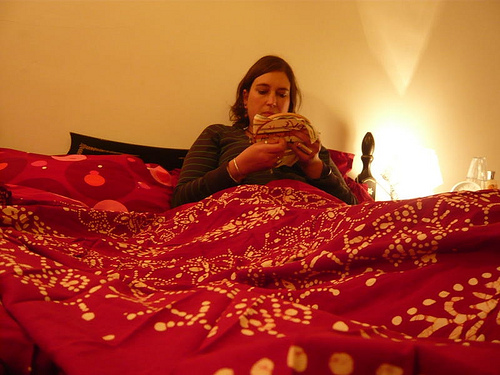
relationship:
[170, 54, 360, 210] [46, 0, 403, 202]
lady on bed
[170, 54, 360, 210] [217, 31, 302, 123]
lady has head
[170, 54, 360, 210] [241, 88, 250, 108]
lady has ear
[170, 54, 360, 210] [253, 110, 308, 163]
lady reads book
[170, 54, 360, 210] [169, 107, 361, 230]
lady wears sweater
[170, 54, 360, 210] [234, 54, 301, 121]
lady has brown hair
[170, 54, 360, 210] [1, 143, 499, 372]
lady in bed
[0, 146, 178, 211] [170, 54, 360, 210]
pillow next lady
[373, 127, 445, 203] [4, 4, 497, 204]
light on wall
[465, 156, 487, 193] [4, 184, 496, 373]
glassware near blanket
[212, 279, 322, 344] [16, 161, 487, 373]
design on bed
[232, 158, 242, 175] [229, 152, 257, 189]
band on wrist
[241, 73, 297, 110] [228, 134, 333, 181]
eyes looking hands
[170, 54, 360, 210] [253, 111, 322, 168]
lady studying book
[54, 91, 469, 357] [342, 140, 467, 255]
bed has lighted corner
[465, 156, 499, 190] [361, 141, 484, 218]
glassware on bedside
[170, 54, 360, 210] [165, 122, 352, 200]
lady in sweater